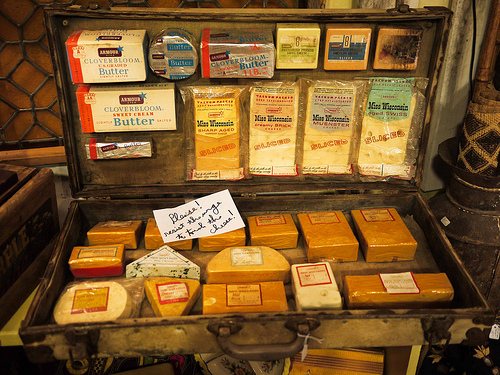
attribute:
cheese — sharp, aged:
[189, 88, 243, 182]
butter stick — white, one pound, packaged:
[76, 86, 181, 133]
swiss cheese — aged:
[248, 85, 298, 178]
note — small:
[151, 188, 247, 246]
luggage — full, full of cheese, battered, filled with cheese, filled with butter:
[20, 6, 493, 363]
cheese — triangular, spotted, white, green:
[124, 243, 199, 282]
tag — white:
[295, 331, 323, 363]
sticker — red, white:
[301, 164, 333, 176]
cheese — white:
[291, 259, 340, 305]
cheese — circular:
[50, 281, 130, 321]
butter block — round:
[148, 31, 200, 83]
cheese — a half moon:
[207, 243, 293, 283]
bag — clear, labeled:
[349, 77, 425, 186]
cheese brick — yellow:
[346, 269, 455, 305]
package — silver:
[82, 141, 156, 160]